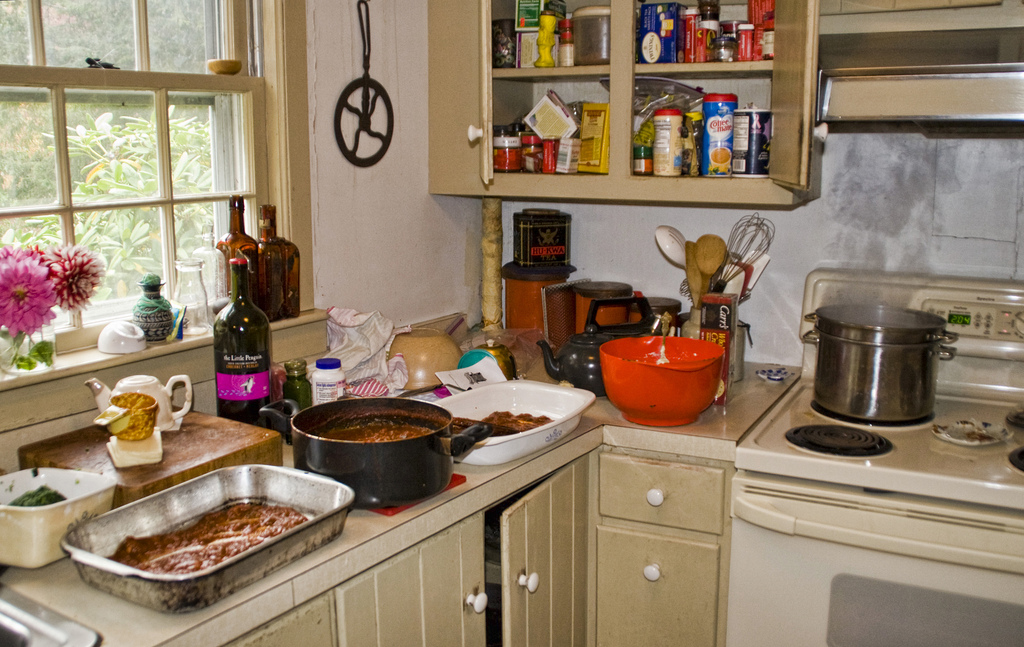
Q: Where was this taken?
A: In a house.